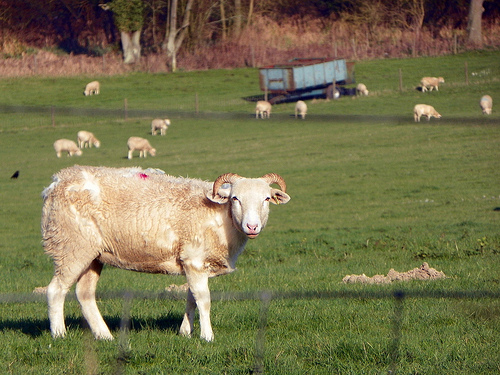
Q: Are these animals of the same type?
A: No, there are both sheep and birds.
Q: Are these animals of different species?
A: Yes, they are sheep and birds.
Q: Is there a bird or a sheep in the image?
A: Yes, there is a sheep.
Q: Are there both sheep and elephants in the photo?
A: No, there is a sheep but no elephants.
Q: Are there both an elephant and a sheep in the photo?
A: No, there is a sheep but no elephants.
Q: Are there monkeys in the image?
A: No, there are no monkeys.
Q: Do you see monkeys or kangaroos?
A: No, there are no monkeys or kangaroos.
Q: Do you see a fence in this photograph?
A: Yes, there is a fence.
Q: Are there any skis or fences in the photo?
A: Yes, there is a fence.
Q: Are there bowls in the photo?
A: No, there are no bowls.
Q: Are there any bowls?
A: No, there are no bowls.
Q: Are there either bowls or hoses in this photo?
A: No, there are no bowls or hoses.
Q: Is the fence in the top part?
A: Yes, the fence is in the top of the image.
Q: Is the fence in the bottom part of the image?
A: No, the fence is in the top of the image.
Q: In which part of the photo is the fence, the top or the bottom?
A: The fence is in the top of the image.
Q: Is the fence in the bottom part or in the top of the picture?
A: The fence is in the top of the image.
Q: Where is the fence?
A: The fence is on the grass.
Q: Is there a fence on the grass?
A: Yes, there is a fence on the grass.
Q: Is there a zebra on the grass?
A: No, there is a fence on the grass.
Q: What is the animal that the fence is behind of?
A: The animal is a goat.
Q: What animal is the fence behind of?
A: The fence is behind the goat.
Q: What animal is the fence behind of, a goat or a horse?
A: The fence is behind a goat.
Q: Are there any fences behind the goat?
A: Yes, there is a fence behind the goat.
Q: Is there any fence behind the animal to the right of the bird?
A: Yes, there is a fence behind the goat.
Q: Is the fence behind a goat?
A: Yes, the fence is behind a goat.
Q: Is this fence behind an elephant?
A: No, the fence is behind a goat.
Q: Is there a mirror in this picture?
A: No, there are no mirrors.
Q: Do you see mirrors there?
A: No, there are no mirrors.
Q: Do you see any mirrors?
A: No, there are no mirrors.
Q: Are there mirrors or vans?
A: No, there are no mirrors or vans.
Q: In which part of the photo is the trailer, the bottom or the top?
A: The trailer is in the top of the image.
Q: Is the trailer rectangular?
A: Yes, the trailer is rectangular.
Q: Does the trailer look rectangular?
A: Yes, the trailer is rectangular.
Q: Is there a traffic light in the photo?
A: No, there are no traffic lights.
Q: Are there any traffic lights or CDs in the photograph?
A: No, there are no traffic lights or cds.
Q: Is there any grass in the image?
A: Yes, there is grass.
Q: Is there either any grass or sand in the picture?
A: Yes, there is grass.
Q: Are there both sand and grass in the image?
A: No, there is grass but no sand.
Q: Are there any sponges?
A: No, there are no sponges.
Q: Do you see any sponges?
A: No, there are no sponges.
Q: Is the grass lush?
A: Yes, the grass is lush.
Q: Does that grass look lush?
A: Yes, the grass is lush.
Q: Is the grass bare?
A: No, the grass is lush.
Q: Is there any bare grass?
A: No, there is grass but it is lush.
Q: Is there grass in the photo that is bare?
A: No, there is grass but it is lush.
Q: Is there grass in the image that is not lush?
A: No, there is grass but it is lush.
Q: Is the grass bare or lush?
A: The grass is lush.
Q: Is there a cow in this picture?
A: No, there are no cows.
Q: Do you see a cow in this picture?
A: No, there are no cows.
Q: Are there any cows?
A: No, there are no cows.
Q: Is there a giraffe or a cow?
A: No, there are no cows or giraffes.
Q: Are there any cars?
A: No, there are no cars.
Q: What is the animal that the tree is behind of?
A: The animal is a goat.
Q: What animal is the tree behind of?
A: The tree is behind the goat.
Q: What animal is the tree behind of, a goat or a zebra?
A: The tree is behind a goat.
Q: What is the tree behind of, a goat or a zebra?
A: The tree is behind a goat.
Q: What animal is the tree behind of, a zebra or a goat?
A: The tree is behind a goat.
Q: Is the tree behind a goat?
A: Yes, the tree is behind a goat.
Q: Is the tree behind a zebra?
A: No, the tree is behind a goat.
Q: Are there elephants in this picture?
A: No, there are no elephants.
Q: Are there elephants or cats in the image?
A: No, there are no elephants or cats.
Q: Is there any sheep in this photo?
A: Yes, there is a sheep.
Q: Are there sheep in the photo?
A: Yes, there is a sheep.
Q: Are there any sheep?
A: Yes, there is a sheep.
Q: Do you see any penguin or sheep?
A: Yes, there is a sheep.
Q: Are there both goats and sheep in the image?
A: Yes, there are both a sheep and goats.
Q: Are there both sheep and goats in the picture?
A: Yes, there are both a sheep and goats.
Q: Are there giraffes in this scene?
A: No, there are no giraffes.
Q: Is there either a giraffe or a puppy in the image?
A: No, there are no giraffes or puppies.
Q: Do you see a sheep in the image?
A: Yes, there is a sheep.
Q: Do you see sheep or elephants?
A: Yes, there is a sheep.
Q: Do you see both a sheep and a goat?
A: Yes, there are both a sheep and a goat.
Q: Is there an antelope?
A: No, there are no antelopes.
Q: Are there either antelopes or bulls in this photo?
A: No, there are no antelopes or bulls.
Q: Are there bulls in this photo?
A: No, there are no bulls.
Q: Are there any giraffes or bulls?
A: No, there are no bulls or giraffes.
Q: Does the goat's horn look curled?
A: Yes, the horn is curled.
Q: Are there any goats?
A: Yes, there is a goat.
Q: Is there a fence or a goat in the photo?
A: Yes, there is a goat.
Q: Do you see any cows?
A: No, there are no cows.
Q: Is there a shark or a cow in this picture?
A: No, there are no cows or sharks.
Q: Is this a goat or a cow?
A: This is a goat.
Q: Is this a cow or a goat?
A: This is a goat.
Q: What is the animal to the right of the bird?
A: The animal is a goat.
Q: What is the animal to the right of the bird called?
A: The animal is a goat.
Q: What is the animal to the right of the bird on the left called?
A: The animal is a goat.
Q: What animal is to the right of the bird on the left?
A: The animal is a goat.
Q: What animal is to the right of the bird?
A: The animal is a goat.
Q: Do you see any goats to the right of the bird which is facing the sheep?
A: Yes, there is a goat to the right of the bird.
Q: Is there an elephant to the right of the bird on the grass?
A: No, there is a goat to the right of the bird.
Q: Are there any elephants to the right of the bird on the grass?
A: No, there is a goat to the right of the bird.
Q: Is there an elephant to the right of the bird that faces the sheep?
A: No, there is a goat to the right of the bird.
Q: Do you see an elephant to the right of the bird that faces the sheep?
A: No, there is a goat to the right of the bird.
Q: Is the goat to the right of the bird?
A: Yes, the goat is to the right of the bird.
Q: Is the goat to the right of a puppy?
A: No, the goat is to the right of the bird.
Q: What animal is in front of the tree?
A: The goat is in front of the tree.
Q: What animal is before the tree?
A: The goat is in front of the tree.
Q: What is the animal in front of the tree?
A: The animal is a goat.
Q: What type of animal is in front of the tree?
A: The animal is a goat.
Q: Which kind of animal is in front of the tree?
A: The animal is a goat.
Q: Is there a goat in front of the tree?
A: Yes, there is a goat in front of the tree.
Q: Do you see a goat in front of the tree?
A: Yes, there is a goat in front of the tree.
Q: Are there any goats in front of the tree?
A: Yes, there is a goat in front of the tree.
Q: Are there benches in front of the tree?
A: No, there is a goat in front of the tree.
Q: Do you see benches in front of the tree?
A: No, there is a goat in front of the tree.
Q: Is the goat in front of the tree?
A: Yes, the goat is in front of the tree.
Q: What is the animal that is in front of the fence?
A: The animal is a goat.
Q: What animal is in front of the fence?
A: The animal is a goat.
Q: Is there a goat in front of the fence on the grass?
A: Yes, there is a goat in front of the fence.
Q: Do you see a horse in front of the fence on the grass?
A: No, there is a goat in front of the fence.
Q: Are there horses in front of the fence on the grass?
A: No, there is a goat in front of the fence.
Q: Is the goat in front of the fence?
A: Yes, the goat is in front of the fence.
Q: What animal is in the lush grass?
A: The animal is a goat.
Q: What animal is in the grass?
A: The animal is a goat.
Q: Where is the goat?
A: The goat is in the grass.